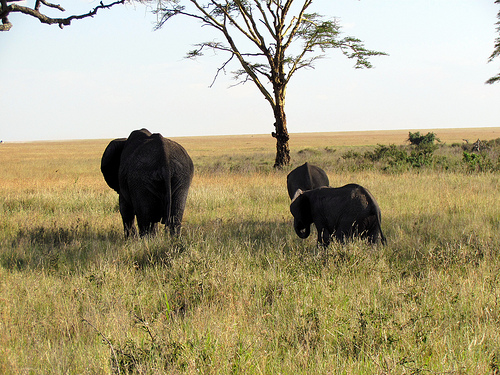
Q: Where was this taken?
A: Savannah.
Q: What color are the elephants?
A: Gray.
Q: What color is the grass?
A: Green.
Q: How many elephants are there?
A: 3.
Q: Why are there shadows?
A: Sunny.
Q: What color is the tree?
A: Brown.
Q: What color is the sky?
A: Blue.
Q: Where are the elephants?
A: In a field.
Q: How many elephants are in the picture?
A: Three.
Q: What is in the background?
A: A tree.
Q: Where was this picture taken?
A: In a field.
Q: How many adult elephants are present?
A: One.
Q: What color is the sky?
A: Light blue.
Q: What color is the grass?
A: Green and brown.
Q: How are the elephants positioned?
A: Away from the camera.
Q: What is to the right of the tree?
A: Bushes.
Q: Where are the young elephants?
A: To the right of the adult elephant.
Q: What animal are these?
A: Elephant.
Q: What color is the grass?
A: Green.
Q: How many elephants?
A: Three.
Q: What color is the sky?
A: White.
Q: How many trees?
A: One.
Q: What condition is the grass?
A: Dry.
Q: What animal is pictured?
A: Elephant.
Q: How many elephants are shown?
A: Three.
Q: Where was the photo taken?
A: Africa.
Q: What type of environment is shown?
A: Savanna.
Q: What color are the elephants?
A: Grey.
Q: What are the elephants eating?
A: Grass.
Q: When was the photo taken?
A: Daylight.